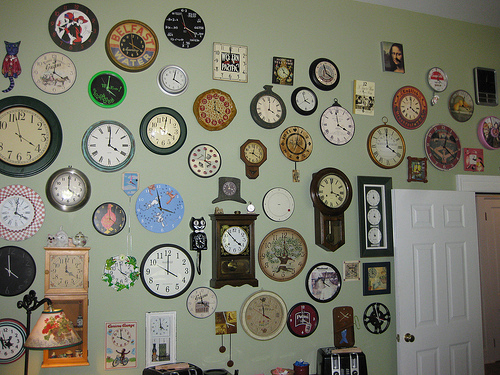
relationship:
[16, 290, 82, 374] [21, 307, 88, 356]
lamp with shade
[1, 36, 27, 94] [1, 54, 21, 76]
cat with shirt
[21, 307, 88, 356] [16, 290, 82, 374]
shade of lamp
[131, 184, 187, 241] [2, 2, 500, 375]
clock on wall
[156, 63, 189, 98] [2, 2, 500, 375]
clock on wall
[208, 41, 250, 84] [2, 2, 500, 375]
clock on wall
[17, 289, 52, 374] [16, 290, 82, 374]
stand of lamp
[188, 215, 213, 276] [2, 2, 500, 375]
clock on wall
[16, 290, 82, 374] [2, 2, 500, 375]
lamp near wall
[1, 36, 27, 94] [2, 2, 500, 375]
cat on wall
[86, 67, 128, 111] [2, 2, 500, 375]
clock on wall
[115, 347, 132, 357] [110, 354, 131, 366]
curious george on bicycle